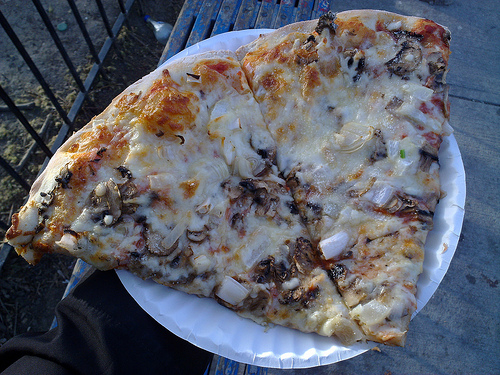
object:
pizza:
[4, 9, 450, 350]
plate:
[116, 28, 467, 371]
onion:
[216, 274, 253, 309]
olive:
[397, 44, 425, 74]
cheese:
[200, 111, 261, 164]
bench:
[49, 0, 338, 375]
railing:
[1, 1, 160, 274]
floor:
[332, 3, 498, 373]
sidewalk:
[271, 3, 499, 374]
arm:
[1, 265, 214, 373]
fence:
[1, 1, 166, 271]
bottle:
[144, 12, 173, 45]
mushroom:
[109, 180, 125, 225]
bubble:
[137, 76, 200, 145]